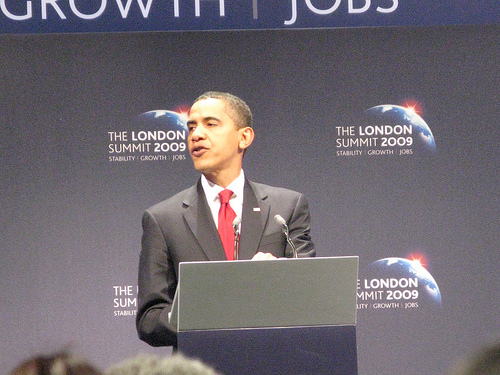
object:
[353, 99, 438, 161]
earth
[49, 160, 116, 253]
blue wall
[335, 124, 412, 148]
white writing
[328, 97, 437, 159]
graphic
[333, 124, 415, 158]
logo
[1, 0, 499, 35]
banner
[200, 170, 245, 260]
shirt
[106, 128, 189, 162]
logo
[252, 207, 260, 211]
lapel pin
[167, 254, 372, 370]
podium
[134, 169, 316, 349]
jacket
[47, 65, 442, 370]
wall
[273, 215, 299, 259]
microphone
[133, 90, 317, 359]
man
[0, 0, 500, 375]
backdrop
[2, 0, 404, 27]
lettering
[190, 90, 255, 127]
hair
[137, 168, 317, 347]
suit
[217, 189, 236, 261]
tie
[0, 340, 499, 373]
audience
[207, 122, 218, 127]
eye